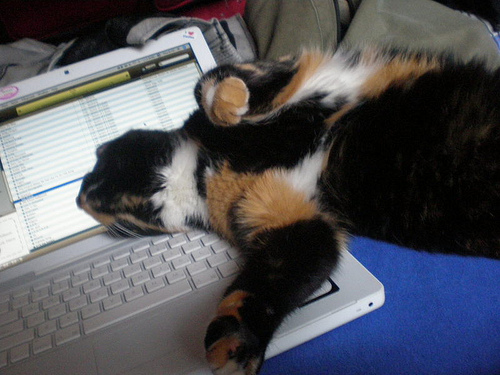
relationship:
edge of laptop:
[260, 243, 386, 361] [0, 25, 386, 373]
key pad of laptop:
[1, 226, 248, 364] [0, 25, 386, 373]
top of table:
[387, 253, 496, 372] [0, 4, 499, 374]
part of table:
[387, 253, 496, 372] [0, 4, 499, 374]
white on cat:
[156, 143, 215, 232] [75, 43, 499, 375]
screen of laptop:
[0, 48, 238, 267] [0, 25, 386, 373]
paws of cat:
[202, 291, 283, 375] [75, 43, 499, 375]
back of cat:
[335, 205, 500, 258] [75, 43, 499, 375]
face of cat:
[75, 131, 179, 237] [75, 43, 499, 375]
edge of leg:
[321, 218, 338, 272] [203, 174, 344, 375]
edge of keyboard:
[4, 347, 212, 373] [1, 226, 248, 364]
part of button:
[164, 285, 192, 291] [83, 281, 202, 335]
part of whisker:
[119, 226, 130, 239] [99, 213, 144, 247]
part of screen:
[121, 76, 170, 109] [0, 48, 238, 267]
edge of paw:
[258, 354, 273, 366] [202, 291, 283, 375]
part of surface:
[385, 324, 443, 357] [267, 229, 496, 374]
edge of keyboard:
[260, 243, 386, 361] [1, 226, 388, 375]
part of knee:
[248, 220, 332, 269] [305, 223, 342, 274]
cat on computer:
[75, 43, 499, 375] [0, 25, 386, 373]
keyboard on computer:
[1, 226, 388, 375] [0, 25, 386, 373]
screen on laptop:
[0, 48, 238, 267] [0, 25, 386, 373]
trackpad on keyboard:
[91, 293, 222, 374] [1, 226, 388, 375]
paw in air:
[198, 72, 252, 131] [167, 23, 422, 120]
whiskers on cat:
[99, 213, 144, 247] [75, 43, 499, 375]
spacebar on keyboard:
[82, 283, 196, 333] [1, 226, 388, 375]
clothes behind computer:
[0, 0, 265, 78] [0, 25, 386, 373]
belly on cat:
[341, 68, 484, 168] [75, 43, 499, 375]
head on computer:
[75, 131, 179, 237] [0, 25, 386, 373]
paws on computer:
[200, 300, 282, 375] [0, 25, 386, 373]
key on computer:
[50, 303, 65, 322] [0, 25, 386, 373]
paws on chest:
[198, 72, 252, 131] [228, 123, 311, 187]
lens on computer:
[3, 139, 21, 258] [0, 25, 386, 373]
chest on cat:
[228, 123, 311, 187] [75, 43, 499, 375]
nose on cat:
[75, 189, 83, 209] [75, 43, 499, 375]